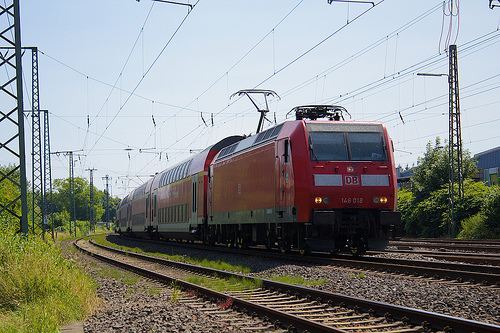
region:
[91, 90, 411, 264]
red train on traveling on rails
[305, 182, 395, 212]
headlights of train are on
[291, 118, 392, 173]
wipes of train are on sides of windshield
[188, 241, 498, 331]
trucks of train has gravel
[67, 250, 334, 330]
bottom of rails have wood planks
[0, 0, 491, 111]
electrical wires tended above rails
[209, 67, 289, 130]
device in train touching wires on top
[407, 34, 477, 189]
pole holding a light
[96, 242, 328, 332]
patches of grass growing on rails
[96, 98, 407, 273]
train is for passengers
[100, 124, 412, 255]
red train on track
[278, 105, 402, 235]
front of red train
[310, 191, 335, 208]
headlight on front of train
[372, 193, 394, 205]
headlight on front of train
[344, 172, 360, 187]
d8 on front of train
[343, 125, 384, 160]
square window on train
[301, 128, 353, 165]
square window on train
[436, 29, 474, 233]
power line on side of track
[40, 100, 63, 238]
power line on side of track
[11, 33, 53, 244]
power line on side of track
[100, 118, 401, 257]
this is a train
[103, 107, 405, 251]
the train is red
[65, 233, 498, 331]
this is a railway truck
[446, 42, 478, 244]
this is an electricity mast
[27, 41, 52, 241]
this is an electricity mast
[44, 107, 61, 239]
this is an electricity mast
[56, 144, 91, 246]
this is an electricity mast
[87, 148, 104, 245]
this is an electricity mast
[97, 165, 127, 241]
this is an electricity mast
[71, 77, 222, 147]
these are electricity lines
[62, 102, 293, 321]
the train is red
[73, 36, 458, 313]
the train is red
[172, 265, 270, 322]
rail road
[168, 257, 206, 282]
rail road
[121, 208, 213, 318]
rail road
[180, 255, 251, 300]
rail road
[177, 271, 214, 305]
rail road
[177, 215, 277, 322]
rail road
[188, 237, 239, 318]
rail road